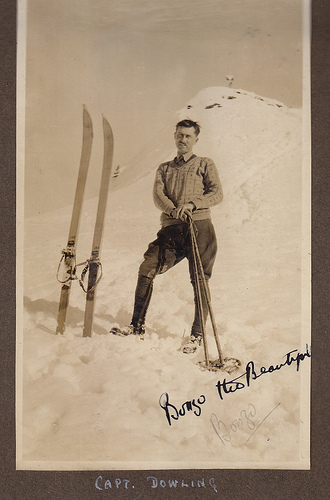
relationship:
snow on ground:
[22, 85, 301, 460] [26, 87, 304, 457]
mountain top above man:
[165, 82, 304, 175] [110, 118, 224, 353]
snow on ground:
[22, 85, 301, 460] [25, 213, 301, 462]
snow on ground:
[130, 401, 132, 407] [22, 350, 317, 467]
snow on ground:
[22, 85, 301, 460] [56, 353, 231, 390]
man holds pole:
[110, 118, 224, 353] [189, 214, 218, 370]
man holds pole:
[110, 118, 224, 353] [189, 219, 225, 366]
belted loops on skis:
[78, 246, 104, 299] [53, 94, 118, 350]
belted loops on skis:
[56, 233, 81, 290] [53, 94, 118, 350]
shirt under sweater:
[175, 151, 192, 159] [156, 165, 211, 214]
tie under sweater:
[177, 157, 187, 164] [156, 165, 211, 214]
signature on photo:
[158, 342, 311, 425] [15, 0, 311, 468]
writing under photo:
[91, 471, 223, 495] [0, 1, 329, 498]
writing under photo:
[159, 340, 311, 447] [0, 1, 329, 498]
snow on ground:
[22, 85, 301, 460] [23, 179, 302, 461]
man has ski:
[130, 106, 238, 362] [77, 113, 114, 339]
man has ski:
[130, 106, 238, 362] [54, 102, 94, 334]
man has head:
[110, 118, 224, 353] [170, 117, 202, 157]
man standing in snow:
[110, 118, 224, 353] [22, 85, 301, 460]